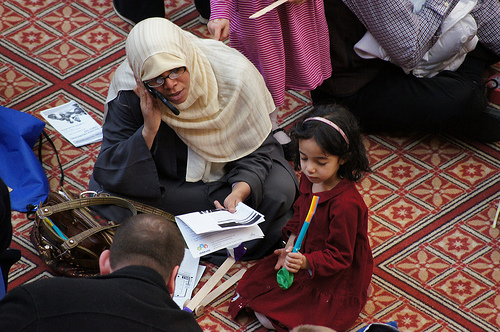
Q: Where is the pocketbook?
A: On the floor.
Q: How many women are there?
A: One.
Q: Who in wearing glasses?
A: The woman.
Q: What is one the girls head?
A: Headband.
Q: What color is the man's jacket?
A: Black.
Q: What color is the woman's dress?
A: Grey.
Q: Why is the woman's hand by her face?
A: Holding phone.